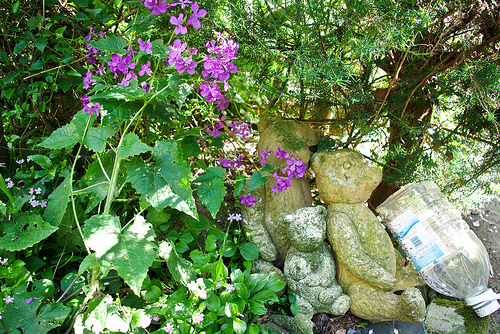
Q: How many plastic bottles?
A: One.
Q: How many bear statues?
A: Three.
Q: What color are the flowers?
A: Purple.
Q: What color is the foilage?
A: Green.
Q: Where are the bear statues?
A: On ground.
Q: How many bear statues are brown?
A: Two.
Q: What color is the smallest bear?
A: Gray.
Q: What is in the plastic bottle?
A: It is empty.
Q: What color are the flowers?
A: Purple.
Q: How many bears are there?
A: Three.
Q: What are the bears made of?
A: Stone.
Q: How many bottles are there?
A: One.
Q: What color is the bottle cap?
A: White.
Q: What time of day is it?
A: Afternoon.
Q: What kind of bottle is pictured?
A: Plastic.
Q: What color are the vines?
A: Green.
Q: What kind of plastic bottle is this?
A: Clear.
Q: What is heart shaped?
A: Leaves.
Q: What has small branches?
A: Tree.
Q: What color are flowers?
A: Purple.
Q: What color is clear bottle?
A: Blue and white.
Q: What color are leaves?
A: Green.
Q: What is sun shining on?
A: Green leaves.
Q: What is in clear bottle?
A: Empty.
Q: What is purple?
A: Flowers.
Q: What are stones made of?
A: Bears.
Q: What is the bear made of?
A: Stone.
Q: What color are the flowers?
A: Purple.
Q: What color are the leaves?
A: Green.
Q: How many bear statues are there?
A: Three.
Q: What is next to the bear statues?
A: A plastic bottle.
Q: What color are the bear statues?
A: Tan.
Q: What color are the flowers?
A: Purple.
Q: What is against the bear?
A: A plastic bottle.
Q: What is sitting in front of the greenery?
A: Bears.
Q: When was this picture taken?
A: Daytime.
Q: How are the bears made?
A: With stone.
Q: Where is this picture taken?
A: In the garden.